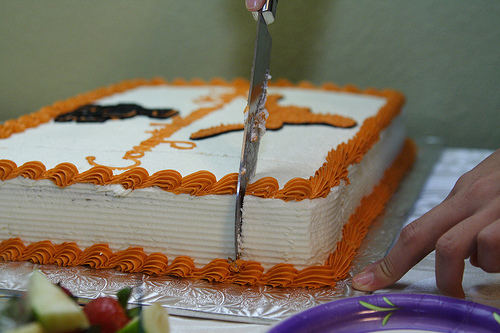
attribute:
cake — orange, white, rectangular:
[2, 77, 418, 289]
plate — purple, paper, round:
[266, 292, 497, 331]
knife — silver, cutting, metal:
[233, 0, 287, 268]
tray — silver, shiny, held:
[2, 130, 446, 321]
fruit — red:
[83, 294, 130, 332]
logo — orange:
[193, 95, 356, 143]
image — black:
[57, 102, 182, 122]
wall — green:
[3, 1, 498, 147]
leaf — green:
[118, 284, 140, 320]